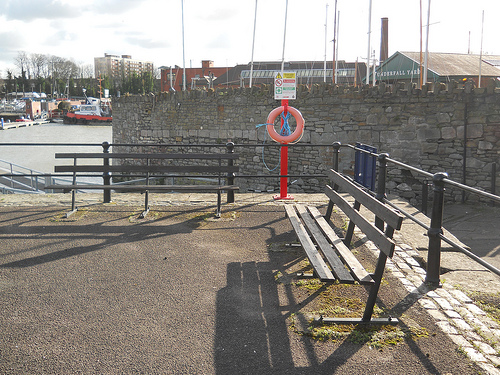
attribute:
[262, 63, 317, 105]
sign — caution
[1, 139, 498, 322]
fence — metal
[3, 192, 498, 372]
stone paving — underneath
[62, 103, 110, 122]
boat — red, white, docked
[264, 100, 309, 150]
ring — red, safety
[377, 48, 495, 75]
roof — rusty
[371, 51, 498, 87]
building — green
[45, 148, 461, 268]
benches — old, wood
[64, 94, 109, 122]
boat — white and red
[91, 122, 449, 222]
metal pole — black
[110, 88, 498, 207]
wall — stone, brick, crumbling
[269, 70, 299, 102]
sign — small, safety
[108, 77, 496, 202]
stone wall — large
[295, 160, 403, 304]
bench — wood, metal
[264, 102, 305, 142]
life saver — red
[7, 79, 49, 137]
boat dock — wood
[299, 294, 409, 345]
grass — green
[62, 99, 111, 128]
boat — red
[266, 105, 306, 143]
life ring — orange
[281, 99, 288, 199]
pole — red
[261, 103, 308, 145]
device — orange, lifesaver, flotation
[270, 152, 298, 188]
pole — red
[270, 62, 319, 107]
sign — white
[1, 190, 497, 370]
pier — small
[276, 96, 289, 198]
pole — red